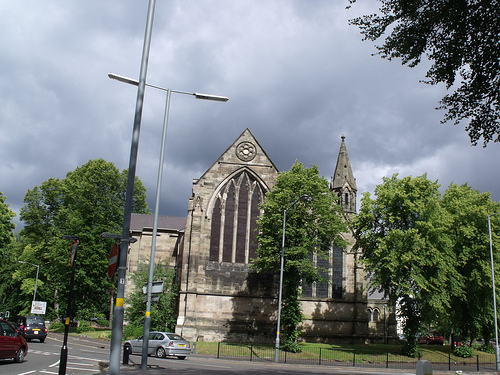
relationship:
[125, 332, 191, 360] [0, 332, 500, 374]
car riding on street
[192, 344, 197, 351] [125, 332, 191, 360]
light on back of car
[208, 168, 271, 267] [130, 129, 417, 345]
windows on front of church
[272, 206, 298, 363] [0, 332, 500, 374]
post on side of street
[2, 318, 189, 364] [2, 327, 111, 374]
cars at intersection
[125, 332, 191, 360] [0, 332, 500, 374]
car driving on street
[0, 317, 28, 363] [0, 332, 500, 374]
car driving on street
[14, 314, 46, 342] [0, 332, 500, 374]
car driving on street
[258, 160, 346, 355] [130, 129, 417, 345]
tree in front of church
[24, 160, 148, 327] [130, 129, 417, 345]
tree on side of church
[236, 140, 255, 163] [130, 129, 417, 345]
circle on top of church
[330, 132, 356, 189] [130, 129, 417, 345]
steeple on top of church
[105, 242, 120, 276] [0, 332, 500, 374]
sign on side of street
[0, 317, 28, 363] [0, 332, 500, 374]
car driving in street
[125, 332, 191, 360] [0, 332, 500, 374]
car driving in street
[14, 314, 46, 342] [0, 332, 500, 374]
car driving in street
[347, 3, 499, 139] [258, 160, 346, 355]
leaves grow on tree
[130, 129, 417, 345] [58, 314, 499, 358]
church on corner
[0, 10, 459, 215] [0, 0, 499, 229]
clouds in sky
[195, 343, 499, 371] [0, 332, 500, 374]
fence near street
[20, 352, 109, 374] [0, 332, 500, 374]
lines marking street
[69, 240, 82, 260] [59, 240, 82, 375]
sign hangs on pole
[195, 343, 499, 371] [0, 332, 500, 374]
fence by street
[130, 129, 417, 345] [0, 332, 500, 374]
church by street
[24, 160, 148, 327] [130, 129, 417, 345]
tree beside church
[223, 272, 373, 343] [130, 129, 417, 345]
shadow on church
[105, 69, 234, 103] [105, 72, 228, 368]
lights on pole